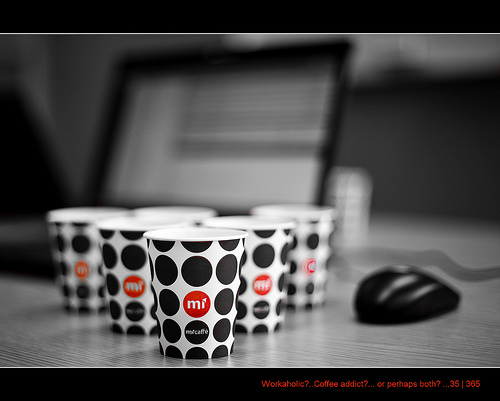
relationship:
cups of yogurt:
[42, 205, 134, 316] [75, 211, 166, 306]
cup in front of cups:
[143, 219, 257, 377] [42, 194, 336, 370]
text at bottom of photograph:
[239, 368, 490, 399] [5, 3, 498, 395]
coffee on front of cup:
[181, 288, 211, 348] [143, 225, 247, 360]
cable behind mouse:
[332, 237, 499, 285] [351, 250, 466, 322]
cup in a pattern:
[97, 217, 194, 337] [42, 192, 340, 372]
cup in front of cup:
[137, 220, 252, 360] [136, 206, 215, 225]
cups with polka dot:
[42, 194, 336, 370] [177, 252, 215, 288]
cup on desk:
[140, 226, 234, 357] [0, 202, 498, 369]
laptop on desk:
[2, 37, 356, 284] [2, 210, 499, 368]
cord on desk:
[326, 237, 488, 287] [4, 225, 499, 400]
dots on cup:
[156, 255, 241, 290] [142, 215, 251, 374]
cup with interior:
[137, 220, 252, 360] [153, 233, 231, 240]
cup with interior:
[149, 222, 241, 357] [104, 215, 175, 225]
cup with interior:
[202, 215, 295, 334] [260, 202, 324, 216]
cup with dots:
[143, 225, 247, 360] [151, 250, 240, 290]